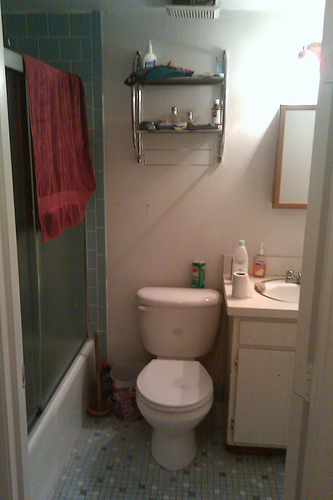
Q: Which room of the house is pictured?
A: It is a bathroom.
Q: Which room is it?
A: It is a bathroom.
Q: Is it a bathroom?
A: Yes, it is a bathroom.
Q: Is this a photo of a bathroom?
A: Yes, it is showing a bathroom.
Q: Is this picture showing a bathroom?
A: Yes, it is showing a bathroom.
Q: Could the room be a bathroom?
A: Yes, it is a bathroom.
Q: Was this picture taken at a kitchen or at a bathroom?
A: It was taken at a bathroom.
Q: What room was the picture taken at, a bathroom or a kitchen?
A: It was taken at a bathroom.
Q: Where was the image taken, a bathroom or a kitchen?
A: It was taken at a bathroom.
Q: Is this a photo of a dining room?
A: No, the picture is showing a bathroom.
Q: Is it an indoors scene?
A: Yes, it is indoors.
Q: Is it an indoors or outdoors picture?
A: It is indoors.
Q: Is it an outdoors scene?
A: No, it is indoors.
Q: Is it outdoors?
A: No, it is indoors.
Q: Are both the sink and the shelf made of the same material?
A: Yes, both the sink and the shelf are made of metal.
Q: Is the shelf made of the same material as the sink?
A: Yes, both the shelf and the sink are made of metal.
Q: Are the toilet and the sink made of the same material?
A: No, the toilet is made of plastic and the sink is made of metal.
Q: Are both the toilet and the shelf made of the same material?
A: No, the toilet is made of plastic and the shelf is made of metal.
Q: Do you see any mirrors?
A: Yes, there is a mirror.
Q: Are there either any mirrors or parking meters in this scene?
A: Yes, there is a mirror.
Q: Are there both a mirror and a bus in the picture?
A: No, there is a mirror but no buses.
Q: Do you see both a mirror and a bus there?
A: No, there is a mirror but no buses.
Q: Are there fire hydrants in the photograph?
A: No, there are no fire hydrants.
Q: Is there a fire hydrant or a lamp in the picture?
A: No, there are no fire hydrants or lamps.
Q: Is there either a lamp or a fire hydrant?
A: No, there are no fire hydrants or lamps.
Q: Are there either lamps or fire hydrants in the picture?
A: No, there are no fire hydrants or lamps.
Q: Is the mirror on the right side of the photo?
A: Yes, the mirror is on the right of the image.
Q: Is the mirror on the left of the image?
A: No, the mirror is on the right of the image.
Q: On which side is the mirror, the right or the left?
A: The mirror is on the right of the image.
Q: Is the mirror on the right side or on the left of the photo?
A: The mirror is on the right of the image.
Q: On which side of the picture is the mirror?
A: The mirror is on the right of the image.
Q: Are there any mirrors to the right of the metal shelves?
A: Yes, there is a mirror to the right of the shelves.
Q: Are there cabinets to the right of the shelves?
A: No, there is a mirror to the right of the shelves.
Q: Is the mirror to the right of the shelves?
A: Yes, the mirror is to the right of the shelves.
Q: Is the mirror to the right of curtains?
A: No, the mirror is to the right of the shelves.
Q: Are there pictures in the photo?
A: No, there are no pictures.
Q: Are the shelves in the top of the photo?
A: Yes, the shelves are in the top of the image.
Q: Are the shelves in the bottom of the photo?
A: No, the shelves are in the top of the image.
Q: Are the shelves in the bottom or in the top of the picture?
A: The shelves are in the top of the image.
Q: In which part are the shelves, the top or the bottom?
A: The shelves are in the top of the image.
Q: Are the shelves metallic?
A: Yes, the shelves are metallic.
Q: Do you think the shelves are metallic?
A: Yes, the shelves are metallic.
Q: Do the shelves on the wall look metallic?
A: Yes, the shelves are metallic.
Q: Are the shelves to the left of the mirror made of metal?
A: Yes, the shelves are made of metal.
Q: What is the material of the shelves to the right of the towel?
A: The shelves are made of metal.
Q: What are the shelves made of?
A: The shelves are made of metal.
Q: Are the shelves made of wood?
A: No, the shelves are made of metal.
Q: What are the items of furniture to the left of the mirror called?
A: The pieces of furniture are shelves.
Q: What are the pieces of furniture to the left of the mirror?
A: The pieces of furniture are shelves.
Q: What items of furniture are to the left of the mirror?
A: The pieces of furniture are shelves.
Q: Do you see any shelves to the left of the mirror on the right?
A: Yes, there are shelves to the left of the mirror.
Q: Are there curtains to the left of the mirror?
A: No, there are shelves to the left of the mirror.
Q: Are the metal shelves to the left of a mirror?
A: Yes, the shelves are to the left of a mirror.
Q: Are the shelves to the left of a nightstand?
A: No, the shelves are to the left of a mirror.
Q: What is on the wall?
A: The shelves are on the wall.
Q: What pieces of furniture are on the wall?
A: The pieces of furniture are shelves.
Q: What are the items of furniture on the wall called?
A: The pieces of furniture are shelves.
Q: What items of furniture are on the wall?
A: The pieces of furniture are shelves.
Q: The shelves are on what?
A: The shelves are on the wall.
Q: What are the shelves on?
A: The shelves are on the wall.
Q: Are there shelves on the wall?
A: Yes, there are shelves on the wall.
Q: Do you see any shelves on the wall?
A: Yes, there are shelves on the wall.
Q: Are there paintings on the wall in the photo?
A: No, there are shelves on the wall.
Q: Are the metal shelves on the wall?
A: Yes, the shelves are on the wall.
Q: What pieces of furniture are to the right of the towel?
A: The pieces of furniture are shelves.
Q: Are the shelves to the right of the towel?
A: Yes, the shelves are to the right of the towel.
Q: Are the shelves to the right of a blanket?
A: No, the shelves are to the right of the towel.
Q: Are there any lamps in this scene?
A: No, there are no lamps.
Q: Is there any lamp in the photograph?
A: No, there are no lamps.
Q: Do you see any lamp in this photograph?
A: No, there are no lamps.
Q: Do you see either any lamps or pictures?
A: No, there are no lamps or pictures.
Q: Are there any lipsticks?
A: No, there are no lipsticks.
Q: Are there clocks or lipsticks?
A: No, there are no lipsticks or clocks.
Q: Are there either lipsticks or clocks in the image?
A: No, there are no lipsticks or clocks.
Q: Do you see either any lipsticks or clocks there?
A: No, there are no lipsticks or clocks.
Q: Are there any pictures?
A: No, there are no pictures.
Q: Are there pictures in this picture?
A: No, there are no pictures.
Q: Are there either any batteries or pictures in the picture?
A: No, there are no pictures or batteries.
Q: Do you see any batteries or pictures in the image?
A: No, there are no pictures or batteries.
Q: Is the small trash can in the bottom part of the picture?
A: Yes, the garbage can is in the bottom of the image.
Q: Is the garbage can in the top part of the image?
A: No, the garbage can is in the bottom of the image.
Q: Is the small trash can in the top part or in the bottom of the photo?
A: The garbage can is in the bottom of the image.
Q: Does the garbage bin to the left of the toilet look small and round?
A: Yes, the garbage bin is small and round.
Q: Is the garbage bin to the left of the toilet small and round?
A: Yes, the garbage bin is small and round.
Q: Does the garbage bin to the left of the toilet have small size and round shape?
A: Yes, the garbage bin is small and round.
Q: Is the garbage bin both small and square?
A: No, the garbage bin is small but round.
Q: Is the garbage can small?
A: Yes, the garbage can is small.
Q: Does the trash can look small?
A: Yes, the trash can is small.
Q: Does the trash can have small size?
A: Yes, the trash can is small.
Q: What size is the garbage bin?
A: The garbage bin is small.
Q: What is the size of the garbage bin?
A: The garbage bin is small.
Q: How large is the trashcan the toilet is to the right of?
A: The garbage can is small.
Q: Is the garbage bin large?
A: No, the garbage bin is small.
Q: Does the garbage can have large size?
A: No, the garbage can is small.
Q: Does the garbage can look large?
A: No, the garbage can is small.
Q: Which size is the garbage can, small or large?
A: The garbage can is small.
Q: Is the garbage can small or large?
A: The garbage can is small.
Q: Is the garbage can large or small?
A: The garbage can is small.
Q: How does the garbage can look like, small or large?
A: The garbage can is small.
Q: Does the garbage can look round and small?
A: Yes, the garbage can is round and small.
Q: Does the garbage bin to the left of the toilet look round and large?
A: No, the trash can is round but small.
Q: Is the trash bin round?
A: Yes, the trash bin is round.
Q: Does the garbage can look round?
A: Yes, the garbage can is round.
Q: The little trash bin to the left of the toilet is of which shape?
A: The garbage can is round.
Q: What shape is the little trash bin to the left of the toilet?
A: The garbage can is round.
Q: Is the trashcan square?
A: No, the trashcan is round.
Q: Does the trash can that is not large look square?
A: No, the garbage bin is round.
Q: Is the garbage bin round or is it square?
A: The garbage bin is round.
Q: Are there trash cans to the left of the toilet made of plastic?
A: Yes, there is a trash can to the left of the toilet.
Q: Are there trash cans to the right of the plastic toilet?
A: No, the trash can is to the left of the toilet.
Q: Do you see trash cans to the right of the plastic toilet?
A: No, the trash can is to the left of the toilet.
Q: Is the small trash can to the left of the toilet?
A: Yes, the trash bin is to the left of the toilet.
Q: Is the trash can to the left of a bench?
A: No, the trash can is to the left of the toilet.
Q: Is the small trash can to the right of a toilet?
A: No, the trash bin is to the left of a toilet.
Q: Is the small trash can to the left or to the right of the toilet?
A: The trash bin is to the left of the toilet.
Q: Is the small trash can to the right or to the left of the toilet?
A: The trash bin is to the left of the toilet.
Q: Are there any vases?
A: No, there are no vases.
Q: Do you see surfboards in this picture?
A: No, there are no surfboards.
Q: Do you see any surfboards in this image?
A: No, there are no surfboards.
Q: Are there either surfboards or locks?
A: No, there are no surfboards or locks.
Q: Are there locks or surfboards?
A: No, there are no surfboards or locks.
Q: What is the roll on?
A: The roll is on the counter.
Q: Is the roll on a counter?
A: Yes, the roll is on a counter.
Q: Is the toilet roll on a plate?
A: No, the toilet roll is on a counter.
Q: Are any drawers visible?
A: No, there are no drawers.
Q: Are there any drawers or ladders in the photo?
A: No, there are no drawers or ladders.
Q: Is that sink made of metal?
A: Yes, the sink is made of metal.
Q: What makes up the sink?
A: The sink is made of metal.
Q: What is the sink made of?
A: The sink is made of metal.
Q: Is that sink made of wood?
A: No, the sink is made of metal.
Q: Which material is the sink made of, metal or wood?
A: The sink is made of metal.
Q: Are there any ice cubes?
A: No, there are no ice cubes.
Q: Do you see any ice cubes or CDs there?
A: No, there are no ice cubes or cds.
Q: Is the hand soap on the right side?
A: Yes, the hand soap is on the right of the image.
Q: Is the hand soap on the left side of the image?
A: No, the hand soap is on the right of the image.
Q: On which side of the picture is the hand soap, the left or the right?
A: The hand soap is on the right of the image.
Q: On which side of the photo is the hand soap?
A: The hand soap is on the right of the image.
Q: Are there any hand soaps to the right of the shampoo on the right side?
A: Yes, there is a hand soap to the right of the shampoo.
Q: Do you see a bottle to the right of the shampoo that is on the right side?
A: No, there is a hand soap to the right of the shampoo.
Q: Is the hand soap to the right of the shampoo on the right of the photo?
A: Yes, the hand soap is to the right of the shampoo.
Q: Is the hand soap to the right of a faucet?
A: No, the hand soap is to the right of the shampoo.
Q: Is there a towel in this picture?
A: Yes, there is a towel.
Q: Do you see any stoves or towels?
A: Yes, there is a towel.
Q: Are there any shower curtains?
A: No, there are no shower curtains.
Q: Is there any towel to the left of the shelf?
A: Yes, there is a towel to the left of the shelf.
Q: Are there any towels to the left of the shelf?
A: Yes, there is a towel to the left of the shelf.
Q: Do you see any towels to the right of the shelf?
A: No, the towel is to the left of the shelf.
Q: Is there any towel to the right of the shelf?
A: No, the towel is to the left of the shelf.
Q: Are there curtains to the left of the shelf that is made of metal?
A: No, there is a towel to the left of the shelf.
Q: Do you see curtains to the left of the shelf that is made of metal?
A: No, there is a towel to the left of the shelf.